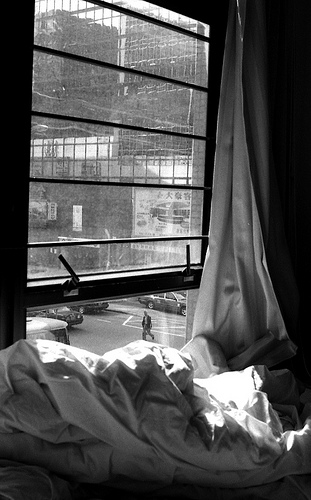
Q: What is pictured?
A: A view out of a window.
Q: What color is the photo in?
A: Black and white.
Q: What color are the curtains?
A: White.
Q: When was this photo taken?
A: During the day.